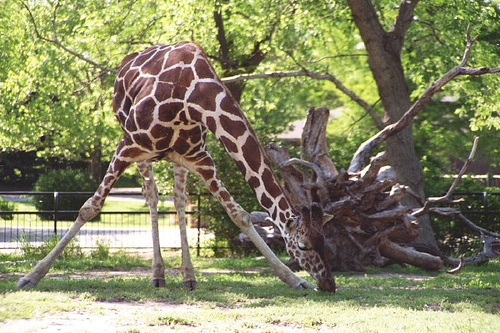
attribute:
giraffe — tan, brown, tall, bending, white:
[89, 51, 332, 295]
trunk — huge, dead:
[287, 127, 422, 280]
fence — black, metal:
[1, 190, 224, 255]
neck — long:
[218, 129, 297, 213]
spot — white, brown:
[138, 64, 179, 95]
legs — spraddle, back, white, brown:
[142, 179, 202, 287]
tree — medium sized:
[287, 20, 473, 269]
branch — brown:
[224, 68, 392, 129]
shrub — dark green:
[34, 162, 107, 223]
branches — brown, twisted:
[359, 160, 500, 237]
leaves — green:
[34, 54, 87, 129]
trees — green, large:
[8, 11, 402, 158]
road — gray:
[2, 217, 231, 252]